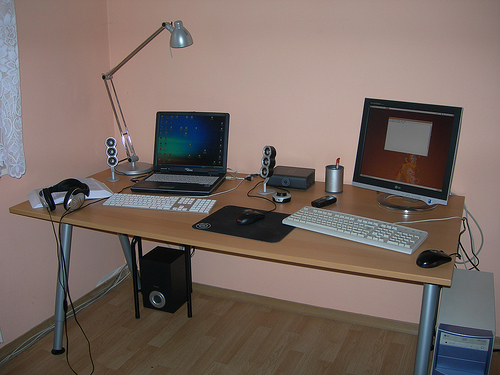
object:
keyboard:
[282, 205, 430, 254]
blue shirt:
[335, 157, 340, 168]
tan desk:
[7, 164, 465, 288]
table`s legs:
[413, 283, 441, 375]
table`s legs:
[117, 234, 141, 291]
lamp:
[100, 20, 193, 176]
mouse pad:
[192, 205, 296, 243]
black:
[248, 216, 251, 221]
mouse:
[235, 208, 264, 224]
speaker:
[105, 136, 121, 182]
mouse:
[272, 191, 292, 203]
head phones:
[38, 178, 91, 211]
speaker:
[139, 245, 187, 313]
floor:
[0, 267, 499, 374]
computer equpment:
[102, 193, 217, 214]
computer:
[130, 111, 230, 196]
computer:
[352, 96, 465, 206]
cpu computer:
[430, 268, 496, 375]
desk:
[9, 168, 465, 374]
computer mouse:
[415, 249, 452, 269]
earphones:
[38, 178, 95, 375]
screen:
[359, 105, 455, 192]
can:
[324, 164, 344, 194]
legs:
[49, 224, 72, 355]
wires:
[394, 191, 484, 271]